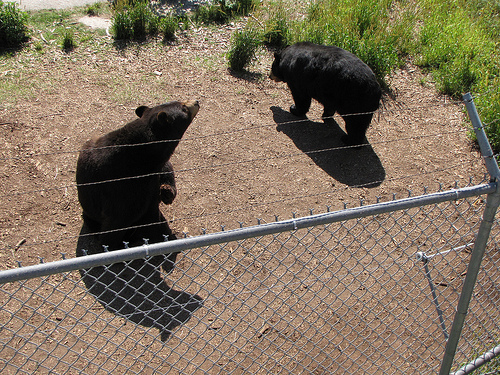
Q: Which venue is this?
A: This is a forest.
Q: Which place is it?
A: It is a forest.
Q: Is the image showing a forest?
A: Yes, it is showing a forest.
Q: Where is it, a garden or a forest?
A: It is a forest.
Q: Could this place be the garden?
A: No, it is the forest.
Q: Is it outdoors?
A: Yes, it is outdoors.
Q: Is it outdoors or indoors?
A: It is outdoors.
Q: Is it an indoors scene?
A: No, it is outdoors.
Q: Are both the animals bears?
A: Yes, all the animals are bears.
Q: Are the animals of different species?
A: No, all the animals are bears.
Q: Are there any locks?
A: No, there are no locks.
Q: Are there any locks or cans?
A: No, there are no locks or cans.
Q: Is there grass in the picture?
A: Yes, there is grass.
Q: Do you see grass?
A: Yes, there is grass.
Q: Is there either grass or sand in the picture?
A: Yes, there is grass.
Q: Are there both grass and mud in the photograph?
A: No, there is grass but no mud.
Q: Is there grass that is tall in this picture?
A: Yes, there is tall grass.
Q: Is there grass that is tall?
A: Yes, there is grass that is tall.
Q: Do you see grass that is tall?
A: Yes, there is grass that is tall.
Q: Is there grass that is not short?
A: Yes, there is tall grass.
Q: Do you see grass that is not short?
A: Yes, there is tall grass.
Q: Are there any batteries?
A: No, there are no batteries.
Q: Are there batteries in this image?
A: No, there are no batteries.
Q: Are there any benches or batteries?
A: No, there are no batteries or benches.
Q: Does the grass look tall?
A: Yes, the grass is tall.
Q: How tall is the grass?
A: The grass is tall.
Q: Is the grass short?
A: No, the grass is tall.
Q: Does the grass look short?
A: No, the grass is tall.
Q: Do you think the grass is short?
A: No, the grass is tall.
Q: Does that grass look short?
A: No, the grass is tall.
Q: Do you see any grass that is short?
A: No, there is grass but it is tall.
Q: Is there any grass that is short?
A: No, there is grass but it is tall.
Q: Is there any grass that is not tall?
A: No, there is grass but it is tall.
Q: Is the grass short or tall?
A: The grass is tall.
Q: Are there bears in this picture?
A: Yes, there is a bear.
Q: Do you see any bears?
A: Yes, there is a bear.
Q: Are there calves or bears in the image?
A: Yes, there is a bear.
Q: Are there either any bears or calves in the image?
A: Yes, there is a bear.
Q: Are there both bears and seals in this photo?
A: No, there is a bear but no seals.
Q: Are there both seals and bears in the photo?
A: No, there is a bear but no seals.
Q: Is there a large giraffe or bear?
A: Yes, there is a large bear.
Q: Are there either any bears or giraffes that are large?
A: Yes, the bear is large.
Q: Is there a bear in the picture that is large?
A: Yes, there is a bear that is large.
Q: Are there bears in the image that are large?
A: Yes, there is a bear that is large.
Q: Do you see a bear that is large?
A: Yes, there is a bear that is large.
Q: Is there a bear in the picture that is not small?
A: Yes, there is a large bear.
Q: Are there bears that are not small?
A: Yes, there is a large bear.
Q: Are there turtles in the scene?
A: No, there are no turtles.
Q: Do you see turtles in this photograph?
A: No, there are no turtles.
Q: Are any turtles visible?
A: No, there are no turtles.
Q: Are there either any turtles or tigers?
A: No, there are no turtles or tigers.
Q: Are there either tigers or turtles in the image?
A: No, there are no turtles or tigers.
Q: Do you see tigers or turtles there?
A: No, there are no turtles or tigers.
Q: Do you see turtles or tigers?
A: No, there are no turtles or tigers.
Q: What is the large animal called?
A: The animal is a bear.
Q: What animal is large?
A: The animal is a bear.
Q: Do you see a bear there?
A: Yes, there is a bear.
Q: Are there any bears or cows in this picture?
A: Yes, there is a bear.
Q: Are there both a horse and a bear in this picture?
A: No, there is a bear but no horses.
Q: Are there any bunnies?
A: No, there are no bunnies.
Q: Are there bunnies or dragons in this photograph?
A: No, there are no bunnies or dragons.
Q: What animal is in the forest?
A: The animal is a bear.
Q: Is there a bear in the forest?
A: Yes, there is a bear in the forest.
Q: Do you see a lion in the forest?
A: No, there is a bear in the forest.